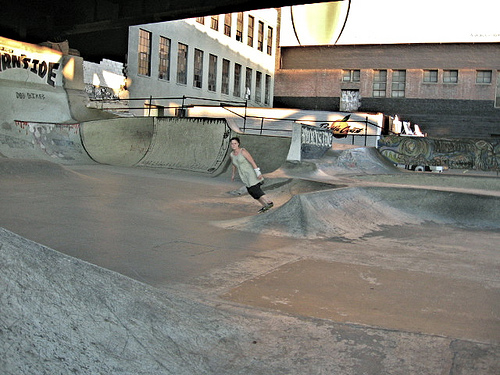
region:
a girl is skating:
[203, 124, 290, 229]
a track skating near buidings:
[16, 103, 496, 374]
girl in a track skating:
[38, 118, 499, 343]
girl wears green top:
[211, 130, 291, 226]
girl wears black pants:
[216, 130, 286, 224]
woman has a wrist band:
[216, 128, 283, 218]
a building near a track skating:
[136, 6, 285, 111]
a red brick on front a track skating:
[281, 30, 499, 128]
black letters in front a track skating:
[1, 35, 66, 102]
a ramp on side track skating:
[89, 75, 319, 135]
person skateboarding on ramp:
[216, 128, 288, 213]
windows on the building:
[127, 37, 275, 104]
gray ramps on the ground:
[95, 122, 221, 175]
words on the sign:
[295, 121, 332, 155]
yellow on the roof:
[295, 13, 337, 37]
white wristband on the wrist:
[246, 162, 263, 182]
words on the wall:
[7, 88, 53, 103]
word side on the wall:
[20, 54, 62, 93]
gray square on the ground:
[145, 218, 220, 276]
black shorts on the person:
[241, 184, 268, 199]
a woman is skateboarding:
[185, 118, 303, 240]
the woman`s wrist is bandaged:
[236, 152, 268, 184]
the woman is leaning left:
[211, 115, 281, 221]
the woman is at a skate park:
[7, 92, 389, 308]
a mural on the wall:
[372, 130, 494, 180]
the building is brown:
[258, 45, 487, 94]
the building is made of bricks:
[285, 43, 468, 94]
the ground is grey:
[46, 148, 335, 316]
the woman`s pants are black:
[228, 175, 273, 209]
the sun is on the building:
[179, 8, 294, 84]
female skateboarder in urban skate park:
[205, 136, 275, 212]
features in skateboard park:
[255, 144, 499, 237]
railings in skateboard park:
[88, 92, 393, 149]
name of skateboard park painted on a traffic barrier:
[287, 122, 335, 163]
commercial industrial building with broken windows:
[125, 5, 280, 106]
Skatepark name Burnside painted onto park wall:
[1, 57, 75, 124]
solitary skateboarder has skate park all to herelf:
[5, 70, 497, 312]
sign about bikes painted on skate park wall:
[15, 88, 45, 102]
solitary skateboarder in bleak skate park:
[1, 41, 494, 374]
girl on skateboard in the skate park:
[212, 129, 279, 230]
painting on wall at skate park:
[0, 46, 70, 105]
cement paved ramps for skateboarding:
[221, 173, 422, 283]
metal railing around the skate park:
[142, 85, 379, 152]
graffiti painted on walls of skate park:
[380, 115, 496, 186]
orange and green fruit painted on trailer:
[316, 107, 378, 150]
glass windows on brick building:
[333, 56, 495, 114]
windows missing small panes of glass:
[156, 50, 223, 91]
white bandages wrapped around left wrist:
[248, 162, 269, 185]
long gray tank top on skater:
[219, 147, 271, 193]